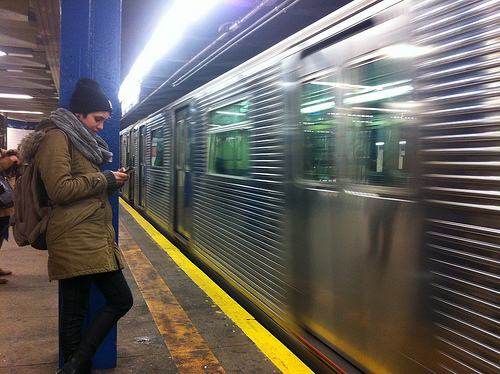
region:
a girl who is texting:
[0, 80, 152, 362]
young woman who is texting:
[4, 67, 155, 372]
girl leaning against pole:
[21, 69, 152, 372]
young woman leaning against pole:
[9, 72, 135, 370]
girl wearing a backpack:
[0, 66, 145, 372]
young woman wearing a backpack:
[0, 71, 138, 373]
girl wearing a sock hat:
[2, 74, 139, 372]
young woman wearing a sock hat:
[2, 76, 137, 372]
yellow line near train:
[110, 181, 287, 360]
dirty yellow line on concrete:
[133, 248, 210, 362]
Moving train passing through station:
[113, 12, 497, 367]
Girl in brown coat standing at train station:
[30, 88, 215, 364]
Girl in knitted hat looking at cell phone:
[53, 83, 140, 200]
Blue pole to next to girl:
[56, 11, 148, 363]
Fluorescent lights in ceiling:
[3, 8, 50, 130]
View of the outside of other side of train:
[366, 125, 420, 180]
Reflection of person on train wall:
[349, 193, 416, 280]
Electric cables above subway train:
[164, 1, 306, 103]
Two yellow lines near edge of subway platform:
[131, 231, 283, 371]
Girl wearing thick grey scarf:
[31, 90, 134, 227]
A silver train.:
[109, 0, 499, 371]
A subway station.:
[1, 3, 496, 371]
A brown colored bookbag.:
[9, 141, 72, 279]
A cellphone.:
[108, 155, 144, 187]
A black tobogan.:
[63, 72, 123, 117]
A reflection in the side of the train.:
[364, 177, 407, 289]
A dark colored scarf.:
[39, 102, 116, 169]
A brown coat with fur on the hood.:
[19, 113, 126, 281]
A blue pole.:
[57, 0, 132, 367]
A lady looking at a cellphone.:
[12, 71, 164, 370]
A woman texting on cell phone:
[10, 76, 133, 373]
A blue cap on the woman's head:
[67, 77, 115, 115]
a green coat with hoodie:
[16, 118, 126, 282]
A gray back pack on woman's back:
[12, 123, 58, 251]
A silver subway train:
[117, 2, 498, 372]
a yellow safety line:
[117, 191, 316, 372]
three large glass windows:
[204, 39, 426, 203]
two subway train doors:
[132, 96, 199, 245]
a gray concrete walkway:
[0, 189, 318, 372]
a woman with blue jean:
[57, 250, 136, 372]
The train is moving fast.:
[118, 2, 497, 369]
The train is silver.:
[118, 8, 498, 372]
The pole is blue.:
[57, 0, 122, 372]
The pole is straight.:
[56, 0, 128, 372]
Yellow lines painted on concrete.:
[113, 190, 306, 372]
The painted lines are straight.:
[110, 187, 318, 372]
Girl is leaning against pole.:
[8, 5, 148, 371]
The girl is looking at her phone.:
[10, 65, 147, 369]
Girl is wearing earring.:
[37, 67, 123, 176]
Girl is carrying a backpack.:
[3, 52, 147, 287]